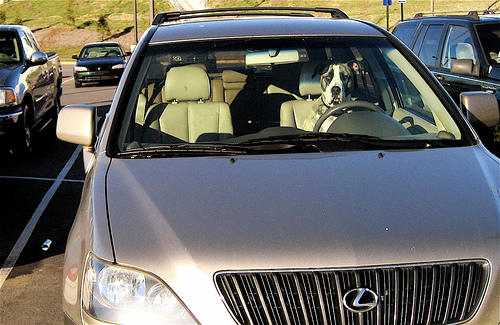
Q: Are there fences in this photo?
A: No, there are no fences.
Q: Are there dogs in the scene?
A: Yes, there is a dog.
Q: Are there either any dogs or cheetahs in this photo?
A: Yes, there is a dog.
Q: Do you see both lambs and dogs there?
A: No, there is a dog but no lambs.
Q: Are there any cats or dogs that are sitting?
A: Yes, the dog is sitting.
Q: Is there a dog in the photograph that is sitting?
A: Yes, there is a dog that is sitting.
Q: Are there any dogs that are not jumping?
A: Yes, there is a dog that is sitting.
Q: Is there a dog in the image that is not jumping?
A: Yes, there is a dog that is sitting.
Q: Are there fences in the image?
A: No, there are no fences.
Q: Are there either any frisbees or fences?
A: No, there are no fences or frisbees.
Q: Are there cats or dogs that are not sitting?
A: No, there is a dog but it is sitting.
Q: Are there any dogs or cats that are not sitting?
A: No, there is a dog but it is sitting.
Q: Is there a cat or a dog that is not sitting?
A: No, there is a dog but it is sitting.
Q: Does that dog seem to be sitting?
A: Yes, the dog is sitting.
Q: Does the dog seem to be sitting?
A: Yes, the dog is sitting.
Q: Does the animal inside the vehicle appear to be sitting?
A: Yes, the dog is sitting.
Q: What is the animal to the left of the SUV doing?
A: The dog is sitting.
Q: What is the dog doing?
A: The dog is sitting.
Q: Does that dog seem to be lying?
A: No, the dog is sitting.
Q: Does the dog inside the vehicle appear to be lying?
A: No, the dog is sitting.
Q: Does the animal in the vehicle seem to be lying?
A: No, the dog is sitting.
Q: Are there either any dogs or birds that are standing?
A: No, there is a dog but it is sitting.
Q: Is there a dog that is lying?
A: No, there is a dog but it is sitting.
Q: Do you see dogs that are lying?
A: No, there is a dog but it is sitting.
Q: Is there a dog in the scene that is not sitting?
A: No, there is a dog but it is sitting.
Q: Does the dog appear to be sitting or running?
A: The dog is sitting.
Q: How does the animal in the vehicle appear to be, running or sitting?
A: The dog is sitting.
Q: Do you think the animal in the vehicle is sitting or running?
A: The dog is sitting.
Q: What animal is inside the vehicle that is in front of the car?
A: The dog is inside the vehicle.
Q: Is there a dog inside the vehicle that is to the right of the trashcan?
A: Yes, there is a dog inside the vehicle.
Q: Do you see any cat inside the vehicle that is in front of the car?
A: No, there is a dog inside the vehicle.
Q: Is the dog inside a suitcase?
A: No, the dog is inside a vehicle.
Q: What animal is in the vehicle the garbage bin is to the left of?
A: The dog is in the vehicle.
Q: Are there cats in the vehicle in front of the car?
A: No, there is a dog in the vehicle.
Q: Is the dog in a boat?
A: No, the dog is in the vehicle.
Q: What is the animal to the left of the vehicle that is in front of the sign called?
A: The animal is a dog.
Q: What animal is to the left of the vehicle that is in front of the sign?
A: The animal is a dog.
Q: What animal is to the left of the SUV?
A: The animal is a dog.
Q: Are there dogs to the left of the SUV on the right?
A: Yes, there is a dog to the left of the SUV.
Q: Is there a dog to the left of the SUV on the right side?
A: Yes, there is a dog to the left of the SUV.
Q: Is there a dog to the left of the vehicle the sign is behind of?
A: Yes, there is a dog to the left of the SUV.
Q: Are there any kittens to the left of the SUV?
A: No, there is a dog to the left of the SUV.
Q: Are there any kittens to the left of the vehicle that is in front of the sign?
A: No, there is a dog to the left of the SUV.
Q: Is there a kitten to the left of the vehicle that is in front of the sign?
A: No, there is a dog to the left of the SUV.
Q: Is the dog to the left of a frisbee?
A: No, the dog is to the left of the SUV.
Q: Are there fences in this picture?
A: No, there are no fences.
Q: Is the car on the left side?
A: Yes, the car is on the left of the image.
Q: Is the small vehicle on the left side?
A: Yes, the car is on the left of the image.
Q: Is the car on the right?
A: No, the car is on the left of the image.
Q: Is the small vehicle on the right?
A: No, the car is on the left of the image.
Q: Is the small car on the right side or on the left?
A: The car is on the left of the image.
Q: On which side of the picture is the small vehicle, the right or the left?
A: The car is on the left of the image.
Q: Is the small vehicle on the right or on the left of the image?
A: The car is on the left of the image.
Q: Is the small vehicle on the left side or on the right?
A: The car is on the left of the image.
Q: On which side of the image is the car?
A: The car is on the left of the image.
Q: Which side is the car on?
A: The car is on the left of the image.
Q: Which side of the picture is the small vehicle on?
A: The car is on the left of the image.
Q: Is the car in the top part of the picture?
A: Yes, the car is in the top of the image.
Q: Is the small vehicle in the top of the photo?
A: Yes, the car is in the top of the image.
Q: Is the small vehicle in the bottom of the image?
A: No, the car is in the top of the image.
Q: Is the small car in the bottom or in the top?
A: The car is in the top of the image.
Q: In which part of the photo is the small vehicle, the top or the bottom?
A: The car is in the top of the image.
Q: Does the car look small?
A: Yes, the car is small.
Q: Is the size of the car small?
A: Yes, the car is small.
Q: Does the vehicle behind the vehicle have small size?
A: Yes, the car is small.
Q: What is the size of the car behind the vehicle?
A: The car is small.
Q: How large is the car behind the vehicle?
A: The car is small.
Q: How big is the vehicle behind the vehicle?
A: The car is small.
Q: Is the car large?
A: No, the car is small.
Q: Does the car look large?
A: No, the car is small.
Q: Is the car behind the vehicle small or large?
A: The car is small.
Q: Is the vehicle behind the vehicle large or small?
A: The car is small.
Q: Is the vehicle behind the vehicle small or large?
A: The car is small.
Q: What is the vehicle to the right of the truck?
A: The vehicle is a car.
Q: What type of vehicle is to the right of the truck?
A: The vehicle is a car.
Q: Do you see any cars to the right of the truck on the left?
A: Yes, there is a car to the right of the truck.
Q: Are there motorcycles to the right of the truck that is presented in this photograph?
A: No, there is a car to the right of the truck.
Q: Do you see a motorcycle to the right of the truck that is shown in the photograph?
A: No, there is a car to the right of the truck.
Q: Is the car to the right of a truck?
A: Yes, the car is to the right of a truck.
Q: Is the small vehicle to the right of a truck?
A: Yes, the car is to the right of a truck.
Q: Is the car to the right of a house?
A: No, the car is to the right of a truck.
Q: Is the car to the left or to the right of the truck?
A: The car is to the right of the truck.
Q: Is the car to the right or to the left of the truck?
A: The car is to the right of the truck.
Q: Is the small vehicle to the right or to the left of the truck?
A: The car is to the right of the truck.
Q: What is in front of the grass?
A: The car is in front of the grass.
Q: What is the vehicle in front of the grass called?
A: The vehicle is a car.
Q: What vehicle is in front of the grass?
A: The vehicle is a car.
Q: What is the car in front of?
A: The car is in front of the grass.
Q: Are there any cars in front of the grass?
A: Yes, there is a car in front of the grass.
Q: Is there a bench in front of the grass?
A: No, there is a car in front of the grass.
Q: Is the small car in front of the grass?
A: Yes, the car is in front of the grass.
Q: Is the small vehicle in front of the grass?
A: Yes, the car is in front of the grass.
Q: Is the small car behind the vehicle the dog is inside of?
A: Yes, the car is behind the vehicle.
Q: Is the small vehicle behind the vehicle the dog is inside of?
A: Yes, the car is behind the vehicle.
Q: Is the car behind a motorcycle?
A: No, the car is behind the vehicle.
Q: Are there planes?
A: No, there are no planes.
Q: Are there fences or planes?
A: No, there are no planes or fences.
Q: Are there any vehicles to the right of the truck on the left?
A: Yes, there is a vehicle to the right of the truck.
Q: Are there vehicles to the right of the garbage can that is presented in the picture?
A: Yes, there is a vehicle to the right of the garbage can.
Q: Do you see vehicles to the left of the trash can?
A: No, the vehicle is to the right of the trash can.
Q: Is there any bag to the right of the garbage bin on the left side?
A: No, there is a vehicle to the right of the trash bin.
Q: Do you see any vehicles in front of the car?
A: Yes, there is a vehicle in front of the car.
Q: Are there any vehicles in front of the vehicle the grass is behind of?
A: Yes, there is a vehicle in front of the car.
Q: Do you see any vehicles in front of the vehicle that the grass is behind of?
A: Yes, there is a vehicle in front of the car.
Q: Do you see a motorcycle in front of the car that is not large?
A: No, there is a vehicle in front of the car.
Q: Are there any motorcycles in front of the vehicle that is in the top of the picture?
A: No, there is a vehicle in front of the car.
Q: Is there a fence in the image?
A: No, there are no fences.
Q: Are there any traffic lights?
A: No, there are no traffic lights.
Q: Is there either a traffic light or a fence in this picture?
A: No, there are no traffic lights or fences.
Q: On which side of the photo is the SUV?
A: The SUV is on the right of the image.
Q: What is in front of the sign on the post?
A: The SUV is in front of the sign.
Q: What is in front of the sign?
A: The SUV is in front of the sign.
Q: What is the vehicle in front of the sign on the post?
A: The vehicle is a SUV.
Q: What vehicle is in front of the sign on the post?
A: The vehicle is a SUV.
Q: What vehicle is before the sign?
A: The vehicle is a SUV.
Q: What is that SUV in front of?
A: The SUV is in front of the sign.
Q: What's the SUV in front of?
A: The SUV is in front of the sign.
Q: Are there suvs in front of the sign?
A: Yes, there is a SUV in front of the sign.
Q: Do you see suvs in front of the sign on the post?
A: Yes, there is a SUV in front of the sign.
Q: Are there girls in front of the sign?
A: No, there is a SUV in front of the sign.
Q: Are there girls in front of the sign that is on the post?
A: No, there is a SUV in front of the sign.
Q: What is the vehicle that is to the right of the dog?
A: The vehicle is a SUV.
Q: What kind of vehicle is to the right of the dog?
A: The vehicle is a SUV.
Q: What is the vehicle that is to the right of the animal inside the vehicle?
A: The vehicle is a SUV.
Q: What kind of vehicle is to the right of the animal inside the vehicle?
A: The vehicle is a SUV.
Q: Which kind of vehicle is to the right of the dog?
A: The vehicle is a SUV.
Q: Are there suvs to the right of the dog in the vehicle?
A: Yes, there is a SUV to the right of the dog.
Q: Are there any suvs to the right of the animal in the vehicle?
A: Yes, there is a SUV to the right of the dog.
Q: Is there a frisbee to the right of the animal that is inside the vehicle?
A: No, there is a SUV to the right of the dog.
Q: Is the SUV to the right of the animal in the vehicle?
A: Yes, the SUV is to the right of the dog.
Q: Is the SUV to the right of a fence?
A: No, the SUV is to the right of the dog.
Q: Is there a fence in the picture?
A: No, there are no fences.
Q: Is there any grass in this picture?
A: Yes, there is grass.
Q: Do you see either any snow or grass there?
A: Yes, there is grass.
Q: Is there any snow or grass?
A: Yes, there is grass.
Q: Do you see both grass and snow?
A: No, there is grass but no snow.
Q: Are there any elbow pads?
A: No, there are no elbow pads.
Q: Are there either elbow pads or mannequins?
A: No, there are no elbow pads or mannequins.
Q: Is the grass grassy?
A: Yes, the grass is grassy.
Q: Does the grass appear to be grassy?
A: Yes, the grass is grassy.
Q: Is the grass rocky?
A: No, the grass is grassy.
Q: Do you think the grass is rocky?
A: No, the grass is grassy.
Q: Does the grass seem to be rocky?
A: No, the grass is grassy.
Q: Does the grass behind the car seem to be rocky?
A: No, the grass is grassy.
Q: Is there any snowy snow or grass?
A: No, there is grass but it is grassy.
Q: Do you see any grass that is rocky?
A: No, there is grass but it is grassy.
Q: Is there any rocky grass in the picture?
A: No, there is grass but it is grassy.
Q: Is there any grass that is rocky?
A: No, there is grass but it is grassy.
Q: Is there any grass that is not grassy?
A: No, there is grass but it is grassy.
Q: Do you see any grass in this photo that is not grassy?
A: No, there is grass but it is grassy.